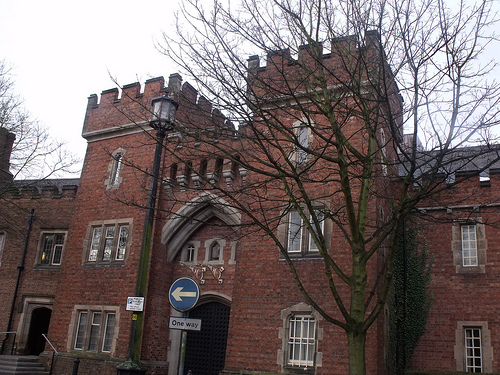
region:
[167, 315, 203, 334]
one way on the sign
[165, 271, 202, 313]
arrow on the sign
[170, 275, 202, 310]
the sign is blue and white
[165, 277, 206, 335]
there is two signs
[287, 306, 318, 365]
window on the building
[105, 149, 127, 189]
window on the building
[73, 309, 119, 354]
windows on the building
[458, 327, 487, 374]
window on the building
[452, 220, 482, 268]
window on the building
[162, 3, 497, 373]
tree in front of the building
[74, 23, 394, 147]
the notched eaves of an armory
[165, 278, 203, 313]
a blue sign with a white arrow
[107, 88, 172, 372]
a tall, black lamp post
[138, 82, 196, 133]
a light on top of a lamp post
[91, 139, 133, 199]
the arched window in a brick wall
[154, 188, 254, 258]
the arch above the armory gates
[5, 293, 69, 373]
stairs to a door in a brick wall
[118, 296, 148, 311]
a white sign on a post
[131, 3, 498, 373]
a tree in front of the armory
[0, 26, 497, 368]
a gothic brick building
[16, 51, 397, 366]
this photo is taken outside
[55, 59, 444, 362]
this is an urban setting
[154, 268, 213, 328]
this is a street sign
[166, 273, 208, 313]
the street sign is pointing left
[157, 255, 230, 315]
the sign is blue and white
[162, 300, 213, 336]
this sign says "one way"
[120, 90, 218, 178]
this is a street pole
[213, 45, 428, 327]
this is a tree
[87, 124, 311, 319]
this is a brick building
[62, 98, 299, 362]
the brick building is red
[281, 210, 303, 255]
window on the building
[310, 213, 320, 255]
window on the building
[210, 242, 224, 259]
window on the building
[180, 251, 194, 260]
window on the building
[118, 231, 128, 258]
window on the building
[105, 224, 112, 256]
window on the building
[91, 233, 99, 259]
window on the building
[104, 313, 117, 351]
window on the building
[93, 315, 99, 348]
window on the building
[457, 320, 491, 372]
the window on a building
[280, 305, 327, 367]
the window on a building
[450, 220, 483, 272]
the window on a building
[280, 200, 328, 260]
the window on a building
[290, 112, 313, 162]
the window on a building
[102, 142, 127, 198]
the window on a building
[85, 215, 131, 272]
windows on a building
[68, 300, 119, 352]
windows on a building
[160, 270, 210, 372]
a One Way sign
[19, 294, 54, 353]
the door to a building